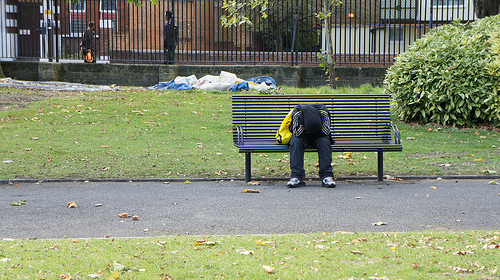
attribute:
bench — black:
[215, 86, 424, 190]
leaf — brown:
[103, 166, 112, 173]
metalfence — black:
[1, 3, 477, 65]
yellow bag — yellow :
[277, 104, 292, 148]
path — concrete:
[1, 180, 497, 236]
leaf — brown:
[434, 158, 454, 171]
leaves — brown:
[66, 197, 142, 224]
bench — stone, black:
[227, 89, 407, 183]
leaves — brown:
[239, 247, 283, 279]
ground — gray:
[2, 171, 492, 247]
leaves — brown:
[312, 237, 368, 261]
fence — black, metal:
[0, 0, 498, 70]